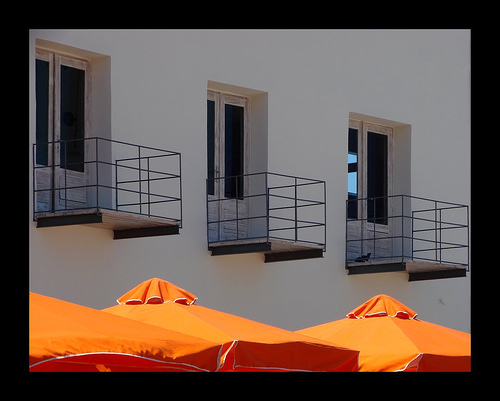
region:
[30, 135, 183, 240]
Balcony of one of the rooms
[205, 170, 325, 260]
Balcony of one of the rooms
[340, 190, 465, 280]
Balcony of one of the rooms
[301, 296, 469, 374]
Orange top of umbrella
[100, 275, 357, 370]
Orange top of umbrella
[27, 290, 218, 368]
Orange top of umbrella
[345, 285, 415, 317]
The highest point of the umbrella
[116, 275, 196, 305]
The highest point of the umbrella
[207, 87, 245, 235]
Wood and black door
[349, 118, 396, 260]
Wood and black door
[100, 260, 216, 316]
orange umbrella on tent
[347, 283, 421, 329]
orange umbrella on tent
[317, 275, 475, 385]
orange tent with umbrella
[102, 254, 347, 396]
orange tent with umbrella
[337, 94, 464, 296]
balcony by apartment doors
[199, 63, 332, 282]
balcony by apartment doors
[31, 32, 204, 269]
balcony by apartment doors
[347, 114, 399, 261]
doors from balcony to apartment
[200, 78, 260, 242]
doors from balcony to apartment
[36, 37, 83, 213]
doors from balcony to apartment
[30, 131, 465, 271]
Balconies of an unfinished house.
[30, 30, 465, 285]
House is painted in white.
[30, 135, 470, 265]
The balconies' fences are in black metal.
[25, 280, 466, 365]
Orange umbrellas are underneath the balconies.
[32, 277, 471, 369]
The umbrellas are those of an outdoor area.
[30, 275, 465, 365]
The orange umbrellas are borded with white color.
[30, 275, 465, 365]
The umbrellas are opened.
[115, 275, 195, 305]
The small umbrella covers the metal tip of the big umbrella.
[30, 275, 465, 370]
Three orange umbrellas in front of the house.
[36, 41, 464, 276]
The three doors are closed.